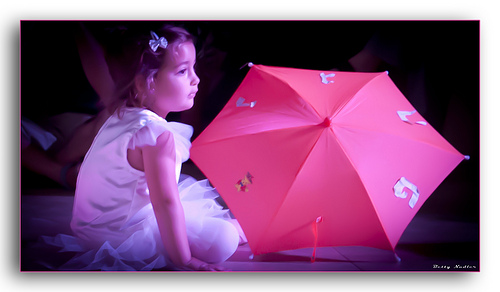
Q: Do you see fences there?
A: No, there are no fences.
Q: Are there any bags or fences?
A: No, there are no fences or bags.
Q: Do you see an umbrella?
A: Yes, there is an umbrella.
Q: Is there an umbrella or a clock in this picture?
A: Yes, there is an umbrella.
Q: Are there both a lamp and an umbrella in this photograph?
A: No, there is an umbrella but no lamps.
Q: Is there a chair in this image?
A: No, there are no chairs.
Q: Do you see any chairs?
A: No, there are no chairs.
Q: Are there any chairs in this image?
A: No, there are no chairs.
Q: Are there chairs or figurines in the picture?
A: No, there are no chairs or figurines.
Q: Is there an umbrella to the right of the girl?
A: Yes, there is an umbrella to the right of the girl.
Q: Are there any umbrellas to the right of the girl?
A: Yes, there is an umbrella to the right of the girl.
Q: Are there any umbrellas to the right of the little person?
A: Yes, there is an umbrella to the right of the girl.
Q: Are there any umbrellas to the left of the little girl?
A: No, the umbrella is to the right of the girl.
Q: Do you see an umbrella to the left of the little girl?
A: No, the umbrella is to the right of the girl.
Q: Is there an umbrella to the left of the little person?
A: No, the umbrella is to the right of the girl.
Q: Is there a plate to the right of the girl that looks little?
A: No, there is an umbrella to the right of the girl.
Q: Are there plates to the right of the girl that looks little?
A: No, there is an umbrella to the right of the girl.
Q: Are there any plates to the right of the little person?
A: No, there is an umbrella to the right of the girl.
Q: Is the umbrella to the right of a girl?
A: Yes, the umbrella is to the right of a girl.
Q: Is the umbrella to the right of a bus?
A: No, the umbrella is to the right of a girl.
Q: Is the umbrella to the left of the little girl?
A: No, the umbrella is to the right of the girl.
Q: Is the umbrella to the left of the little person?
A: No, the umbrella is to the right of the girl.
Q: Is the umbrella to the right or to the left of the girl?
A: The umbrella is to the right of the girl.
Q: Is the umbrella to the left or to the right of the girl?
A: The umbrella is to the right of the girl.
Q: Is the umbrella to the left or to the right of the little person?
A: The umbrella is to the right of the girl.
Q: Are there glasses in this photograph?
A: No, there are no glasses.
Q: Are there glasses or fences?
A: No, there are no glasses or fences.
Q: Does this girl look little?
A: Yes, the girl is little.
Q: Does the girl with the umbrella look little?
A: Yes, the girl is little.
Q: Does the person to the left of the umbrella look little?
A: Yes, the girl is little.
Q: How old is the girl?
A: The girl is little.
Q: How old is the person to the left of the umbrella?
A: The girl is little.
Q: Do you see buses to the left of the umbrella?
A: No, there is a girl to the left of the umbrella.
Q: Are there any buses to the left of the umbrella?
A: No, there is a girl to the left of the umbrella.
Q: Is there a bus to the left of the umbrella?
A: No, there is a girl to the left of the umbrella.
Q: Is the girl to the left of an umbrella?
A: Yes, the girl is to the left of an umbrella.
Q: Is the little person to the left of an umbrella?
A: Yes, the girl is to the left of an umbrella.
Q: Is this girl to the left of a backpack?
A: No, the girl is to the left of an umbrella.